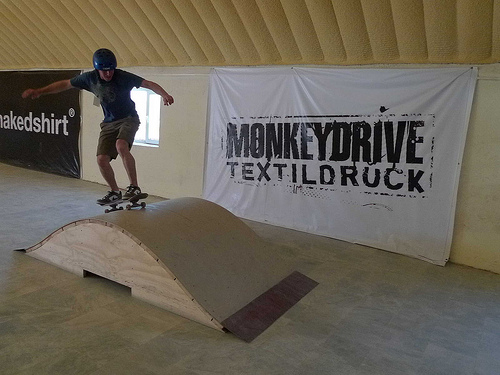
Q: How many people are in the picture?
A: One.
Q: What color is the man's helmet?
A: Blue.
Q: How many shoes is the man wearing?
A: Two.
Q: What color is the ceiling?
A: Yellow.